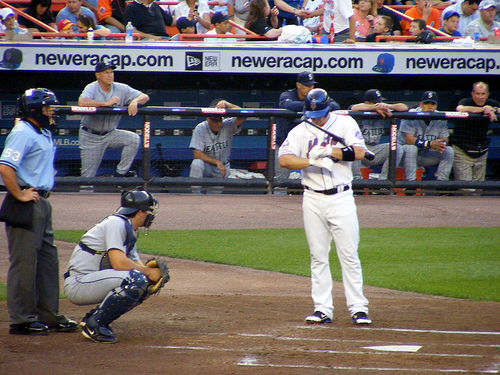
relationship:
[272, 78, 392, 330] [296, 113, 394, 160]
mets player at bat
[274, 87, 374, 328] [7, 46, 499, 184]
player in dugout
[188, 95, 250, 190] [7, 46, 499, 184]
players in dugout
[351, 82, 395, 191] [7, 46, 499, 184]
players in dugout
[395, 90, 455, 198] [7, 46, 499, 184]
player in dugout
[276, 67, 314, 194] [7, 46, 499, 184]
players in dugout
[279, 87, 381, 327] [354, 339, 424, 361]
player next to home plate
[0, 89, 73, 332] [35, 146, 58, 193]
man wearing a shirt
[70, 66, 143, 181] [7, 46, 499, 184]
player on dugout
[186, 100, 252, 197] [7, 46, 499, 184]
players on dugout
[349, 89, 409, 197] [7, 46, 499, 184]
players on dugout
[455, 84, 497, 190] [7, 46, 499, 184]
player on dugout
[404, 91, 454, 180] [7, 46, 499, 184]
player on dugout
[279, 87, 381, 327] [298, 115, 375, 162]
player holding bat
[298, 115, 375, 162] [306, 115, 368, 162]
bat under arm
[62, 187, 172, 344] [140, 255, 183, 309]
player wearing catcher's mitt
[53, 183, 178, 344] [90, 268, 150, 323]
player wearing pads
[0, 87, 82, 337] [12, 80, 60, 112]
man wearing dark helmet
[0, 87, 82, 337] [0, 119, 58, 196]
man wearing shirt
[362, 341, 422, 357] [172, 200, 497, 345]
home plate on baseball field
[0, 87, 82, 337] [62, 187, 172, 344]
man standing behind player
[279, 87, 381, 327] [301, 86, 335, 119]
player wearing helmet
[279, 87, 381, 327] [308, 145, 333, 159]
player wearing glove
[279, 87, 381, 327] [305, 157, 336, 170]
player wearing glove